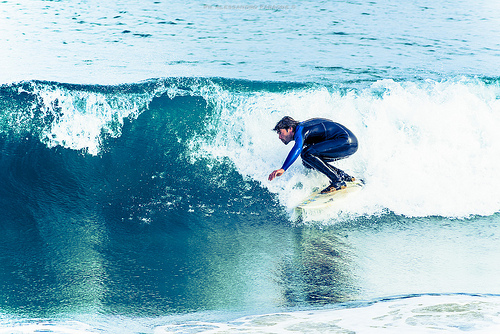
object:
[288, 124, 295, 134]
ear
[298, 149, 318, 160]
knees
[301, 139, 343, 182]
leg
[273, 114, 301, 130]
hair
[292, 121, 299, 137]
collar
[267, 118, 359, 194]
body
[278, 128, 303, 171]
arm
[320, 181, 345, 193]
foot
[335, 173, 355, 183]
foot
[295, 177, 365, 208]
surfboard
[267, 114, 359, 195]
person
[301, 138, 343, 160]
thigh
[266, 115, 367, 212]
surfing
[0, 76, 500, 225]
wave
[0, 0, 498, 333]
ocean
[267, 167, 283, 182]
hand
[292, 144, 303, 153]
elbow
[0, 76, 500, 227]
crest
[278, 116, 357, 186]
suit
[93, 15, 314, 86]
body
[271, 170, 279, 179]
finger